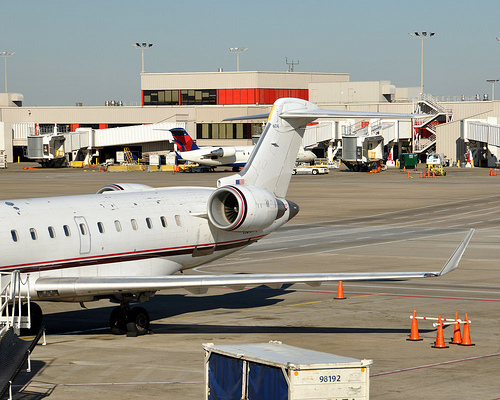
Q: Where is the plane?
A: At an airport.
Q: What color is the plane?
A: White.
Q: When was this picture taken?
A: During the day.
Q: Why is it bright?
A: It's daytime.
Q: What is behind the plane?
A: A building.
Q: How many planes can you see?
A: One.